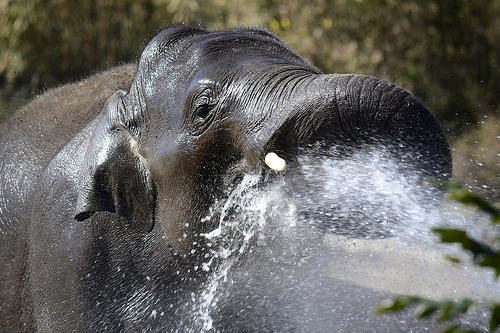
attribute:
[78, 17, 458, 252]
head — dark brown, of the elephant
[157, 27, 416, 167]
wrinkly skin — grey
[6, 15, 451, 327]
elephant — dark brown, right front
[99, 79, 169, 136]
skin — wrinkly, grey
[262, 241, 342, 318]
droplets — water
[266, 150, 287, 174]
tusk — of the elephant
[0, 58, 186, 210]
back — of an elephant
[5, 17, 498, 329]
elephant — big, grey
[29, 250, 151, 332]
arm — elephant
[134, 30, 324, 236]
head — of the elephant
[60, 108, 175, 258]
ear — of the elephant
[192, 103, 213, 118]
eye — of the elephant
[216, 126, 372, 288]
water — up under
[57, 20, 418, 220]
head — top, an elephant's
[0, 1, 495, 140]
trees — forest of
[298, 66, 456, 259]
trunk — dark brown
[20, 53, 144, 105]
back — of the elephant